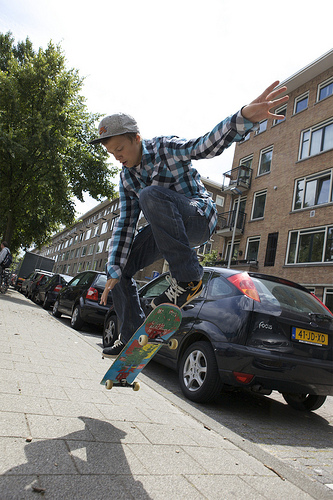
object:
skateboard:
[98, 298, 184, 393]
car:
[129, 254, 331, 414]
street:
[5, 254, 329, 484]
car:
[55, 269, 158, 344]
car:
[34, 274, 76, 314]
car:
[18, 269, 54, 296]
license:
[293, 331, 328, 350]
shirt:
[94, 112, 254, 282]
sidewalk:
[0, 290, 315, 498]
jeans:
[100, 189, 212, 344]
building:
[225, 52, 330, 407]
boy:
[94, 77, 298, 362]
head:
[96, 116, 143, 171]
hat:
[92, 112, 135, 144]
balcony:
[221, 165, 251, 192]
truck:
[13, 245, 59, 300]